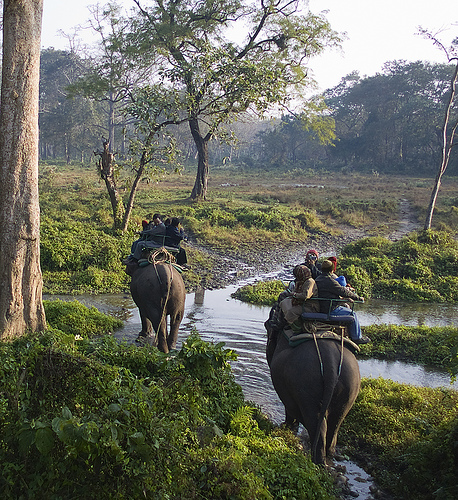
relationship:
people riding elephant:
[267, 249, 368, 344] [270, 320, 361, 466]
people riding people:
[267, 249, 368, 344] [122, 213, 190, 267]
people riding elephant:
[122, 213, 190, 267] [125, 263, 184, 348]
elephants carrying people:
[133, 243, 379, 406] [256, 255, 401, 317]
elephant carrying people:
[270, 320, 361, 466] [315, 260, 372, 346]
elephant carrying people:
[130, 257, 185, 353] [165, 214, 192, 269]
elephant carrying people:
[130, 257, 185, 353] [123, 214, 168, 265]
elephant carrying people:
[270, 320, 361, 466] [279, 265, 322, 338]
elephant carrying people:
[270, 320, 361, 466] [267, 249, 368, 344]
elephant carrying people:
[130, 257, 185, 353] [120, 212, 189, 275]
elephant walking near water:
[130, 257, 185, 353] [119, 229, 455, 463]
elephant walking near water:
[270, 320, 361, 466] [119, 229, 455, 463]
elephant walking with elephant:
[270, 320, 361, 466] [131, 233, 186, 354]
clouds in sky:
[44, 2, 456, 116] [41, 2, 457, 115]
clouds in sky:
[36, 0, 456, 113] [41, 2, 457, 115]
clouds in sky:
[44, 2, 456, 116] [0, 0, 458, 121]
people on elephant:
[267, 249, 368, 344] [270, 320, 361, 466]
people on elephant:
[120, 208, 191, 268] [126, 259, 183, 351]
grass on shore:
[378, 227, 450, 303] [3, 153, 456, 496]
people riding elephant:
[122, 213, 190, 267] [120, 252, 185, 353]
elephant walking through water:
[266, 309, 361, 466] [43, 177, 456, 496]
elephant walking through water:
[130, 257, 185, 353] [43, 177, 456, 496]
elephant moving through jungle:
[270, 320, 361, 466] [2, 0, 457, 494]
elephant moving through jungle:
[120, 257, 189, 361] [2, 0, 457, 494]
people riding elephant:
[122, 213, 190, 267] [130, 257, 185, 353]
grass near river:
[0, 295, 352, 499] [110, 270, 456, 491]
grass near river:
[69, 426, 196, 475] [49, 193, 447, 493]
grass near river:
[208, 193, 303, 237] [188, 261, 279, 371]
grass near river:
[192, 357, 283, 434] [214, 329, 296, 417]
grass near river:
[149, 419, 237, 490] [49, 193, 447, 493]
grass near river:
[345, 381, 454, 491] [49, 193, 447, 493]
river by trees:
[49, 193, 447, 493] [45, 39, 457, 177]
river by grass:
[49, 193, 447, 493] [2, 335, 302, 497]